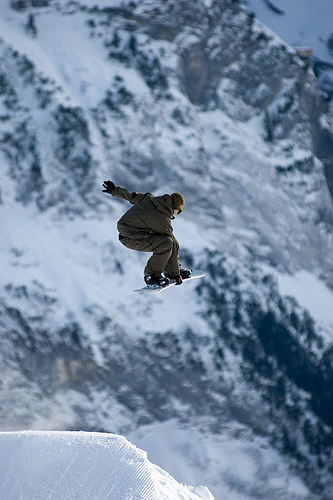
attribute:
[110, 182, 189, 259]
sweater — grey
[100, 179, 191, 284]
skier — airborne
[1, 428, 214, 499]
snow — white, big, chunk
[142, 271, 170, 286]
shoe — black, winter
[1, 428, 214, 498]
snow wedge — large